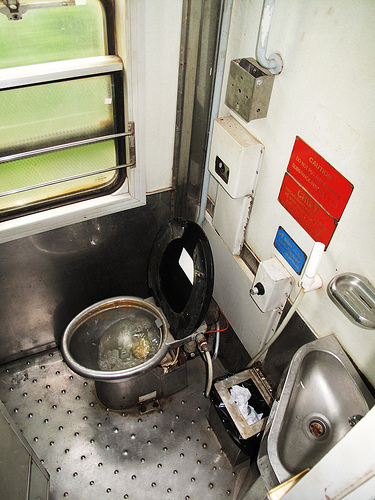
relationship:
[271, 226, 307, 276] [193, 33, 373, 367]
sign on wall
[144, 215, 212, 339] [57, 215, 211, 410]
seat on toilet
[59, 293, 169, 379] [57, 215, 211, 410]
bowl on toilet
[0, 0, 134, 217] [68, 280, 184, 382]
window next to toilet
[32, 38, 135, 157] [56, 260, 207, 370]
window next to toilet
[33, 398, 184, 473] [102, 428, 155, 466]
rivets on floor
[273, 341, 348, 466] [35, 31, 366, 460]
sink next to toilet